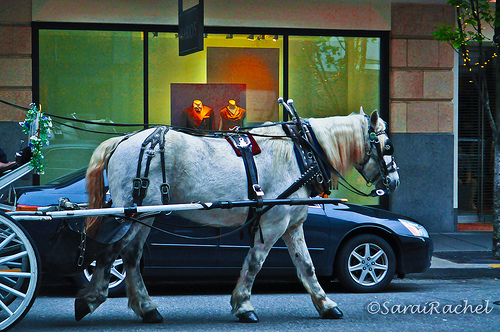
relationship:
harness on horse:
[273, 95, 338, 193] [70, 97, 405, 324]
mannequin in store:
[179, 98, 217, 133] [0, 1, 484, 232]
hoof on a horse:
[233, 310, 258, 325] [70, 97, 405, 324]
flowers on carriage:
[20, 99, 50, 172] [0, 94, 43, 330]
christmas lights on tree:
[454, 2, 499, 74] [426, 0, 498, 262]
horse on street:
[70, 97, 405, 324] [3, 262, 498, 327]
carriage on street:
[0, 98, 53, 330] [3, 262, 498, 327]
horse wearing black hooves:
[70, 97, 405, 324] [65, 299, 363, 324]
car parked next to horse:
[1, 150, 433, 292] [83, 122, 403, 310]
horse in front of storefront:
[70, 97, 405, 324] [21, 7, 401, 217]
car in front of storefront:
[1, 149, 434, 296] [21, 7, 401, 217]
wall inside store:
[44, 42, 354, 107] [8, 4, 469, 249]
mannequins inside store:
[180, 96, 250, 129] [8, 4, 469, 249]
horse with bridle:
[70, 97, 405, 324] [358, 114, 400, 196]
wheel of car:
[334, 234, 395, 290] [13, 194, 439, 286]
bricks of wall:
[382, 29, 493, 139] [388, 6, 464, 135]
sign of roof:
[178, 4, 203, 53] [25, 0, 393, 32]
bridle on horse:
[358, 130, 401, 197] [70, 97, 405, 324]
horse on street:
[71, 106, 398, 324] [19, 273, 484, 328]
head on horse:
[356, 107, 430, 207] [23, 80, 405, 319]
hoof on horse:
[315, 300, 346, 317] [71, 88, 431, 317]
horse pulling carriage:
[70, 97, 405, 324] [0, 113, 42, 328]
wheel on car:
[72, 239, 144, 297] [1, 150, 433, 292]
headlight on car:
[396, 216, 429, 238] [1, 150, 433, 292]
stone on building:
[390, 101, 407, 131] [2, 1, 494, 234]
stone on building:
[407, 100, 439, 132] [2, 1, 494, 234]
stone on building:
[439, 101, 454, 131] [2, 1, 494, 234]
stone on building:
[391, 67, 424, 99] [2, 1, 494, 234]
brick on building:
[422, 69, 454, 101] [2, 1, 494, 234]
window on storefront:
[37, 22, 391, 219] [8, 19, 483, 218]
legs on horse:
[220, 215, 361, 324] [70, 97, 405, 324]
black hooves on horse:
[74, 302, 96, 322] [70, 97, 405, 324]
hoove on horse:
[141, 307, 163, 322] [70, 97, 405, 324]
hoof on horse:
[233, 310, 258, 325] [70, 97, 405, 324]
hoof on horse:
[320, 307, 343, 318] [70, 97, 405, 324]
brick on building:
[422, 66, 460, 106] [2, 1, 494, 234]